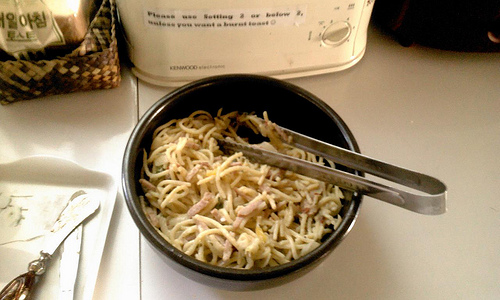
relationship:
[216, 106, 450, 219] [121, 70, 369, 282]
tongs inside bowl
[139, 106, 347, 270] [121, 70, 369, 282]
pasta inside bowl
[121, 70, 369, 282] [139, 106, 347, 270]
bowl full of pasta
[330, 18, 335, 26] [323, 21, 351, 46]
number near handle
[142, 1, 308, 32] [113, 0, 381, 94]
sign stuck to toaster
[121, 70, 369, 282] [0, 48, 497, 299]
bowl on top of counter